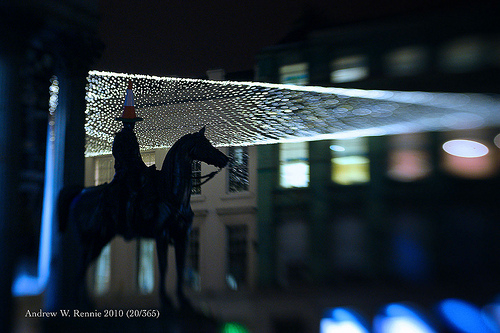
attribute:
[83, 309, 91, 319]
white letter — print style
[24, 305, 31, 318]
letter — white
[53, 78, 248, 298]
figure — small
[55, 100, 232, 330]
statue — horse, rider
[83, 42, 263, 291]
building — rectangular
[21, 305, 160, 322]
letter — white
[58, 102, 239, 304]
statue — large 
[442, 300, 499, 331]
light — blue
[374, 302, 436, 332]
light — blue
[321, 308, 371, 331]
light — blue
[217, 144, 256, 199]
window — rectangular, reflective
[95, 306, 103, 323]
letter — white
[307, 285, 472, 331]
lights — blurred, blue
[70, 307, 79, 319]
letter — white, print style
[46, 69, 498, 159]
lights — white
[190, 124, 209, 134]
statue — pointy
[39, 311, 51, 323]
letter — white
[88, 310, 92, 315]
letter — white, print style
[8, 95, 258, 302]
statue — shadowed